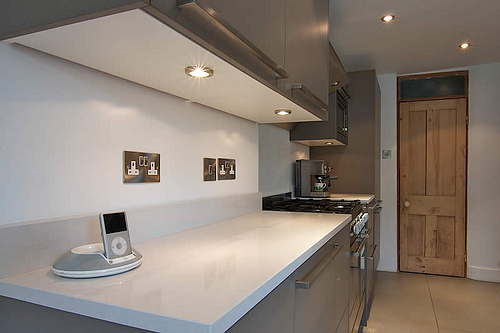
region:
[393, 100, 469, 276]
Light brown wooden door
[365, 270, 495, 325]
Tan tile floor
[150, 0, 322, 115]
Steel cabinets with handles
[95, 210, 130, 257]
Silver iPod with white trackpad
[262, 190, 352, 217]
Black metal stovetop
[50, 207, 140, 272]
Gray and white iPod charging station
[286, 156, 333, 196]
Coffee brewing machine with pot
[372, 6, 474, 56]
Turned on ceiling lights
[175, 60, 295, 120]
Two turned on lights beneath cabinets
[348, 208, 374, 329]
Oven with stove control dials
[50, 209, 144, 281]
apple charging station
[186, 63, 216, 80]
recessed lighting fixture lit up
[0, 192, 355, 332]
long white kitchen counter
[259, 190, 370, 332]
gas burning kitchen stove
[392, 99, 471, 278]
wood kitchen entry door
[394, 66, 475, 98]
small window above door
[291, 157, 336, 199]
coffee pot on far small counter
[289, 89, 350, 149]
wall mounted microwave above stove area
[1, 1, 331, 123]
cabinets above counter area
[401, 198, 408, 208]
white knob on door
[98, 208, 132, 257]
silver ipod on counter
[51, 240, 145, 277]
ipod in speaker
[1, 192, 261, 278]
white backsplash above counter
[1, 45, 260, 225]
smooth white wall above backsplash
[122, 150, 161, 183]
small picture hanging on wall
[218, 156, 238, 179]
picture next to picture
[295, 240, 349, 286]
silver metal handle below counter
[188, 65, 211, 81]
recessed light above counter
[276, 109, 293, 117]
light is on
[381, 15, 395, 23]
recessed light on ceiling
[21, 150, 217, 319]
an ipod on a dock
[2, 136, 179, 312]
an ipod plugged into a dock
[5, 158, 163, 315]
silver ipod plugged into a dock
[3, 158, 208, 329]
an ipod plugged into speakers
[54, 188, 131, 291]
a silver ipod plugged into speakers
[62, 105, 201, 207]
an electric plug above the counter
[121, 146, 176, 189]
electric plug on the wall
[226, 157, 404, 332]
a kitchen gas stove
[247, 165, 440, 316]
a stove and oven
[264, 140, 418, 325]
a silver stove and oven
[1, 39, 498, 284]
The wall is white.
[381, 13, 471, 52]
Lights are in the ceiling.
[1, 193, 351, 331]
The countertop is white.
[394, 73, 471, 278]
The door is made of wood.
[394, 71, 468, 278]
The door is brown.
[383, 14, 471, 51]
The lights are on.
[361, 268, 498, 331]
The floor is tan.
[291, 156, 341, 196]
A coffee maker is in the picture.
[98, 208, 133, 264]
The ipod is gray.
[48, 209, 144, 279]
The ipod is in a dock.